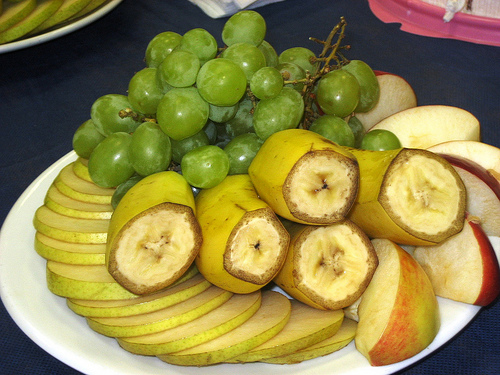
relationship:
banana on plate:
[106, 170, 203, 296] [0, 150, 498, 374]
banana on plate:
[248, 128, 360, 225] [0, 150, 498, 374]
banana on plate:
[356, 147, 468, 247] [0, 150, 498, 374]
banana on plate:
[197, 175, 293, 295] [0, 150, 498, 374]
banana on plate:
[275, 216, 379, 312] [0, 150, 498, 374]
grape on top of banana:
[194, 56, 249, 108] [193, 172, 293, 295]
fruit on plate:
[35, 157, 354, 364] [0, 146, 497, 375]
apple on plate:
[411, 219, 496, 306] [0, 146, 497, 375]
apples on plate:
[55, 164, 272, 334] [0, 146, 497, 375]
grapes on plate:
[65, 7, 403, 189] [0, 146, 497, 375]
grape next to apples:
[85, 141, 136, 189] [52, 160, 119, 206]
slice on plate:
[378, 233, 421, 340] [0, 150, 498, 374]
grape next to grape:
[311, 71, 373, 121] [344, 52, 382, 114]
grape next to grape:
[344, 52, 382, 114] [311, 108, 368, 158]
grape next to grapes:
[205, 60, 249, 107] [154, 84, 212, 142]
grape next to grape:
[177, 137, 269, 203] [102, 118, 181, 188]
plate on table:
[0, 150, 498, 374] [1, 2, 498, 374]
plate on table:
[1, 0, 117, 53] [1, 2, 498, 374]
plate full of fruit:
[0, 146, 497, 375] [167, 82, 434, 314]